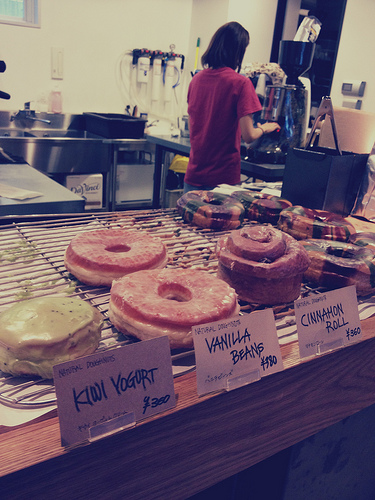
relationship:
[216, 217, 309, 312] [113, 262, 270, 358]
cinnamon roll beside doughnut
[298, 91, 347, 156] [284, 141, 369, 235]
tongs in a container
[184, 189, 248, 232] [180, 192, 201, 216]
donut has chocolate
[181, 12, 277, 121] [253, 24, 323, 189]
girl by coffeemaker